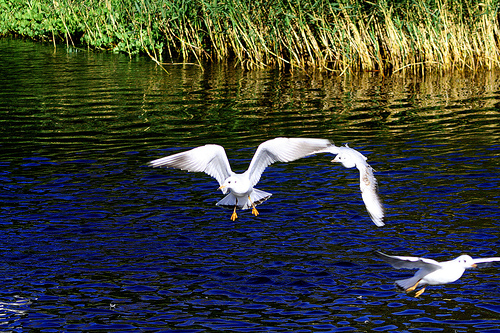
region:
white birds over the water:
[66, 98, 496, 309]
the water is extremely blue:
[42, 222, 332, 297]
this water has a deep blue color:
[47, 237, 337, 313]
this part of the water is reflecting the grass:
[160, 15, 485, 125]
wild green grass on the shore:
[7, 0, 149, 45]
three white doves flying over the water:
[142, 123, 495, 296]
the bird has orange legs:
[222, 194, 267, 223]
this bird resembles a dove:
[137, 119, 303, 228]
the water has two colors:
[12, 64, 140, 245]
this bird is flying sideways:
[295, 132, 407, 231]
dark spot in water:
[14, 189, 49, 225]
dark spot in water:
[175, 237, 220, 281]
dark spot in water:
[246, 247, 303, 277]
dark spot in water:
[250, 282, 297, 329]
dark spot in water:
[154, 291, 201, 316]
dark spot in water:
[43, 277, 95, 326]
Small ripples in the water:
[11, 268, 108, 305]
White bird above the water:
[367, 216, 488, 300]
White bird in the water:
[307, 111, 403, 237]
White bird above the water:
[117, 83, 340, 248]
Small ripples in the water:
[18, 79, 68, 130]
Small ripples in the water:
[22, 190, 104, 269]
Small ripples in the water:
[140, 202, 204, 262]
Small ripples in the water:
[281, 183, 328, 238]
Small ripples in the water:
[393, 108, 491, 243]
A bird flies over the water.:
[140, 133, 340, 223]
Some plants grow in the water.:
[0, 1, 498, 71]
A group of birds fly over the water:
[133, 128, 498, 301]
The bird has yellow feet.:
[222, 206, 262, 216]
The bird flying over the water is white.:
[140, 130, 336, 220]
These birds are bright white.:
[140, 132, 495, 312]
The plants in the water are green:
[0, 0, 495, 62]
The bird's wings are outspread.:
[140, 128, 342, 225]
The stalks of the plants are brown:
[212, 28, 499, 70]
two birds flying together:
[140, 126, 393, 231]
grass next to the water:
[2, 12, 497, 74]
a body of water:
[3, 37, 496, 331]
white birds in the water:
[148, 135, 492, 297]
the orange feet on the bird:
[223, 201, 262, 221]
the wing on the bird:
[253, 133, 331, 178]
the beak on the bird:
[216, 183, 230, 190]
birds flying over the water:
[152, 127, 494, 299]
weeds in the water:
[2, 11, 488, 68]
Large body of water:
[58, 75, 130, 128]